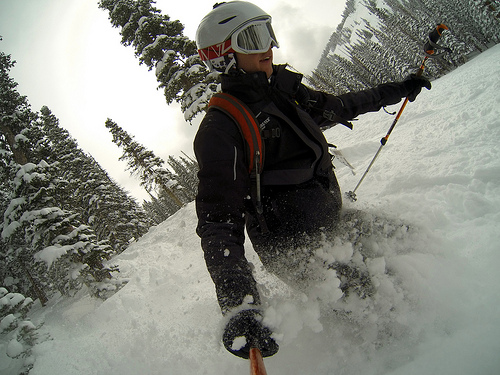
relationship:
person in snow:
[193, 2, 431, 358] [31, 51, 499, 374]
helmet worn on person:
[194, 4, 270, 64] [193, 2, 431, 358]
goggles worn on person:
[231, 22, 278, 53] [193, 2, 431, 358]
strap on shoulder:
[211, 96, 264, 170] [191, 94, 266, 170]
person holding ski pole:
[193, 2, 431, 358] [344, 21, 446, 204]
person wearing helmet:
[193, 2, 431, 358] [194, 4, 270, 64]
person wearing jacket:
[193, 2, 431, 358] [195, 72, 399, 274]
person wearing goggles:
[193, 2, 431, 358] [231, 22, 278, 53]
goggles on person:
[231, 22, 278, 53] [193, 2, 431, 358]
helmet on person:
[194, 4, 270, 64] [193, 2, 431, 358]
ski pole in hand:
[344, 21, 446, 204] [403, 70, 432, 104]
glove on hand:
[221, 313, 279, 362] [225, 314, 277, 360]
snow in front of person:
[259, 210, 383, 316] [193, 2, 431, 358]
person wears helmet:
[193, 2, 431, 358] [194, 4, 270, 64]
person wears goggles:
[193, 2, 431, 358] [231, 22, 278, 53]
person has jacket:
[193, 2, 431, 358] [195, 72, 399, 274]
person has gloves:
[193, 2, 431, 358] [217, 73, 435, 360]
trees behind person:
[0, 0, 198, 303] [193, 2, 431, 358]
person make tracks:
[193, 2, 431, 358] [132, 204, 198, 285]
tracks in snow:
[132, 204, 198, 285] [31, 51, 499, 374]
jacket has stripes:
[195, 72, 399, 274] [230, 149, 240, 188]